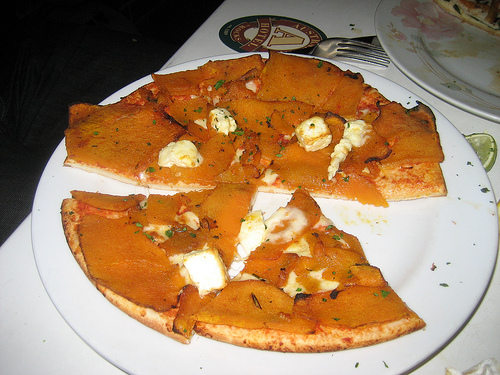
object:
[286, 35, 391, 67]
fork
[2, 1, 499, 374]
table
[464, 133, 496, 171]
lime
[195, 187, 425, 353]
pizza slice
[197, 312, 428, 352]
crust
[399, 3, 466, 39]
flower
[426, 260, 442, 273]
flakes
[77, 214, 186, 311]
topping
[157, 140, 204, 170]
cheese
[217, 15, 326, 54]
logo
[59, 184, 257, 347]
pizza slices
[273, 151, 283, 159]
flakes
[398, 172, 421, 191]
sauce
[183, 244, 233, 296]
topping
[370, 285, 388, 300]
topping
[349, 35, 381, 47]
knife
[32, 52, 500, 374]
plate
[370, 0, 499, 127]
plate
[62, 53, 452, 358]
pizza